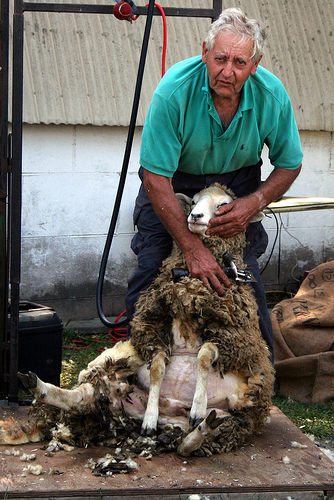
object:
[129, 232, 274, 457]
fur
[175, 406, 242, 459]
leg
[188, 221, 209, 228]
mouth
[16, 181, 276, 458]
sheep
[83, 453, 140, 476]
fur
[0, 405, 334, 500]
table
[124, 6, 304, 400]
man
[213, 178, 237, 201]
wool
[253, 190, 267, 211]
light spot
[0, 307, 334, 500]
ground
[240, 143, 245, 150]
blue emblem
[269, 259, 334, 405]
burlap sack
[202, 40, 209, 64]
ear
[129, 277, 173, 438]
leg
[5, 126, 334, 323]
wall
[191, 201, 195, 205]
eye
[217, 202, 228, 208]
eye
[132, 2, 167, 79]
wire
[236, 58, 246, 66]
eyes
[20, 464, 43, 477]
sheep wool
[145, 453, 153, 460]
sheep wool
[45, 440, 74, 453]
sheep wool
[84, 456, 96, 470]
sheep wool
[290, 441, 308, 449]
sheep wool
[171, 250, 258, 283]
razor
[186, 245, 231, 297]
hand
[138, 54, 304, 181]
shirt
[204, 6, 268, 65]
hair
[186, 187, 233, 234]
face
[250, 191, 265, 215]
wrist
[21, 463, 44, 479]
hair